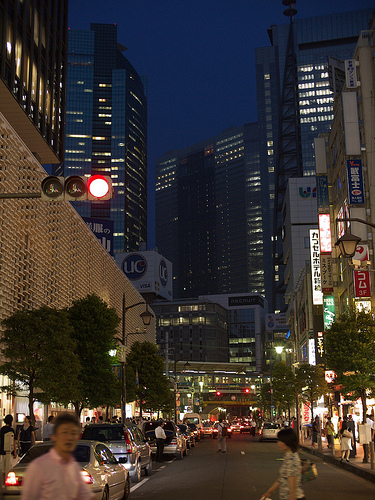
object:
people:
[337, 421, 353, 464]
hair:
[277, 422, 295, 448]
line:
[129, 473, 150, 492]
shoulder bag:
[297, 460, 318, 484]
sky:
[85, 8, 355, 266]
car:
[6, 440, 130, 498]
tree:
[0, 304, 79, 447]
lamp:
[138, 311, 154, 326]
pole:
[121, 292, 128, 443]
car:
[86, 420, 154, 481]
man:
[152, 417, 165, 464]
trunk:
[141, 418, 179, 447]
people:
[213, 411, 226, 451]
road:
[65, 411, 375, 500]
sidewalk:
[280, 424, 373, 482]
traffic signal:
[38, 171, 117, 200]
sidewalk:
[5, 419, 149, 476]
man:
[22, 415, 98, 500]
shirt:
[21, 445, 91, 499]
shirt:
[277, 454, 302, 499]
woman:
[260, 426, 305, 500]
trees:
[0, 291, 119, 426]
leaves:
[6, 292, 119, 409]